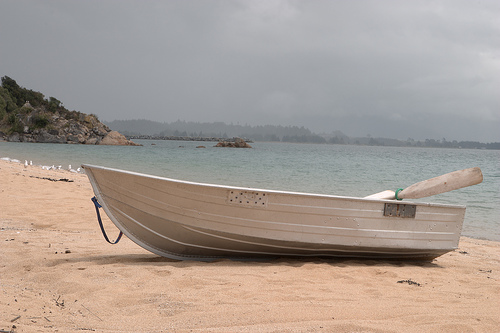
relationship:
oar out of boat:
[377, 149, 477, 206] [110, 166, 474, 276]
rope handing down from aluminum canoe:
[91, 193, 124, 245] [76, 157, 487, 265]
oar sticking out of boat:
[360, 168, 483, 200] [77, 161, 465, 265]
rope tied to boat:
[89, 201, 116, 243] [161, 180, 279, 241]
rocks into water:
[4, 77, 129, 141] [2, 110, 498, 251]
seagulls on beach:
[3, 150, 76, 176] [22, 194, 136, 331]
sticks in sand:
[2, 271, 85, 326] [1, 177, 281, 331]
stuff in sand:
[37, 225, 91, 274] [1, 177, 281, 331]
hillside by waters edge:
[0, 71, 137, 144] [2, 163, 499, 253]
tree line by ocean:
[103, 117, 321, 141] [1, 140, 499, 237]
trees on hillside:
[0, 76, 57, 102] [0, 77, 137, 145]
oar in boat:
[360, 168, 483, 200] [77, 161, 465, 265]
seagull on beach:
[21, 158, 30, 168] [0, 169, 91, 331]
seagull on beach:
[65, 160, 75, 175] [0, 169, 91, 331]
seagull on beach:
[39, 161, 49, 170] [0, 169, 91, 331]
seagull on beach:
[77, 163, 82, 172] [0, 169, 91, 331]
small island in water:
[213, 133, 251, 149] [273, 150, 390, 177]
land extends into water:
[2, 71, 129, 155] [239, 141, 360, 190]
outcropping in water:
[215, 136, 252, 146] [1, 143, 498, 235]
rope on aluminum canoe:
[91, 193, 124, 245] [76, 157, 487, 265]